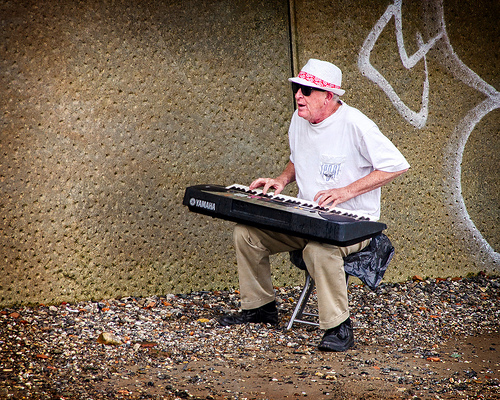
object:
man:
[217, 58, 408, 352]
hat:
[288, 58, 346, 96]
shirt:
[287, 98, 410, 240]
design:
[318, 160, 344, 182]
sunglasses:
[291, 82, 326, 97]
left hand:
[313, 188, 352, 209]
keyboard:
[223, 183, 378, 223]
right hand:
[249, 177, 285, 196]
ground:
[0, 273, 500, 400]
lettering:
[190, 198, 216, 211]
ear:
[324, 91, 333, 105]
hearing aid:
[324, 99, 329, 105]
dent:
[287, 1, 299, 113]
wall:
[0, 0, 500, 305]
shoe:
[317, 320, 354, 352]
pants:
[234, 218, 371, 330]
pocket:
[319, 153, 343, 182]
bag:
[289, 233, 396, 291]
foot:
[218, 307, 278, 325]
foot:
[317, 323, 355, 351]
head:
[295, 61, 341, 120]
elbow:
[397, 160, 409, 176]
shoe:
[218, 307, 279, 327]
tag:
[354, 1, 498, 266]